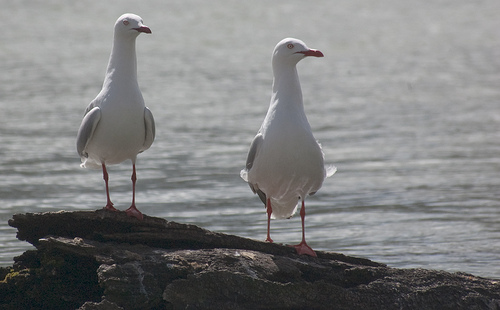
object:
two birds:
[76, 12, 157, 221]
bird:
[239, 36, 339, 258]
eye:
[287, 42, 293, 49]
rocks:
[0, 209, 499, 308]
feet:
[287, 239, 319, 257]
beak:
[300, 49, 325, 58]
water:
[1, 1, 499, 280]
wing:
[77, 106, 103, 157]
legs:
[263, 195, 275, 244]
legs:
[100, 163, 116, 208]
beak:
[133, 26, 153, 34]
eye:
[121, 19, 130, 25]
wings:
[144, 106, 156, 153]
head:
[271, 37, 324, 68]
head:
[113, 13, 153, 44]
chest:
[267, 124, 315, 167]